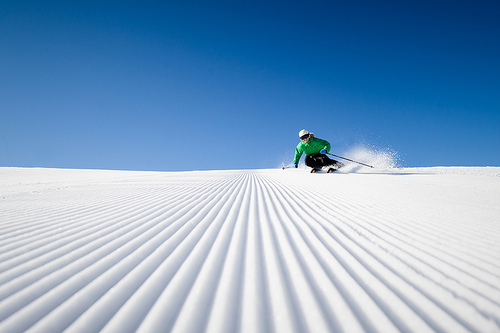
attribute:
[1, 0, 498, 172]
sky — blue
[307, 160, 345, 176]
skis — black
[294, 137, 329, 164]
jacket — grey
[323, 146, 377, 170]
ski pole — black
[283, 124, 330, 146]
goggles — black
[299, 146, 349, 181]
pants — black